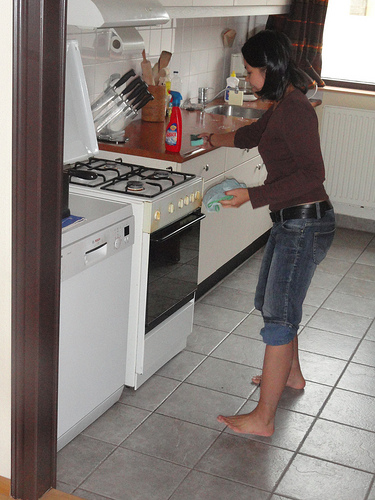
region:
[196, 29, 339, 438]
a woman wearing blue jeans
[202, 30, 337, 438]
a woman wearing a brown shirt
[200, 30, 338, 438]
a woman standing with bare feet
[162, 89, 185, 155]
a red and blue bottle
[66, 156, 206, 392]
a white kitchen stove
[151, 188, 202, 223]
a group of dials on a stove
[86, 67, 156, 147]
knives in a knife rack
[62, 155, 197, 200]
four burners on a stove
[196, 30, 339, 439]
a woman wearing a bracelet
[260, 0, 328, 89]
brown and orange kitchen curtains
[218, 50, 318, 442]
a woman cleaning the kitchen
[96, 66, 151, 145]
a set of knives in the kitchen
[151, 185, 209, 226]
control knobs on the front of a stove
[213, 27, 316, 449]
a woman wearing no shoes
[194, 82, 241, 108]
a chrome kitchen faucet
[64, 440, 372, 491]
light colored ceramic tile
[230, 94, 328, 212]
a long sleeved top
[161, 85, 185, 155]
a spray bottle of cleanser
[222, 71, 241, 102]
a bottle of dishwashing soap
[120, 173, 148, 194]
front left stove burner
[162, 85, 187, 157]
A RED AND BLUE BOTTLE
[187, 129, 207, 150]
a turquoise and green sponge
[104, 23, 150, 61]
a paper towel rack and paper towels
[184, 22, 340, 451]
a woman cleaning a kitchen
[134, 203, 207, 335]
the black door of an oven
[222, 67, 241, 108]
a clear bottle of cleaner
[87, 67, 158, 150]
a set of kitchen knives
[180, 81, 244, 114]
a kitchen faucet over a sink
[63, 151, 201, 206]
four stove top burners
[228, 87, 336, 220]
a brown shirt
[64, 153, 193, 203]
Burners on a stove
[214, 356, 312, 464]
A person who is barefoot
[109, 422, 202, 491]
A section of tile flooring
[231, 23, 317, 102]
A woman with black hair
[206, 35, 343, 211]
A woman in a brown shirt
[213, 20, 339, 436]
A woman with jeans rolled up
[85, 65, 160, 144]
A knife holder on a counter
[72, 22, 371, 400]
A woman working in a kitchen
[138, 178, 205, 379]
The front of a stove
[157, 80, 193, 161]
A bottle of cleaner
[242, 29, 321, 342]
Rolled up jeans to work.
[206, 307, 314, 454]
Bare feet tile floor.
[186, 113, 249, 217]
Cleaning tools her hands.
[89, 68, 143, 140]
Different size knives available.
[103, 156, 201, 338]
Apartment size stove shown.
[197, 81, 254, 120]
Stainless steel sink faucet.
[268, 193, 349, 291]
Black leather belt hold pants.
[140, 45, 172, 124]
Cooking utensils ready needed.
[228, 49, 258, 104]
White coffee maker corner.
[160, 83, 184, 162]
Cleaner bottle on counter.